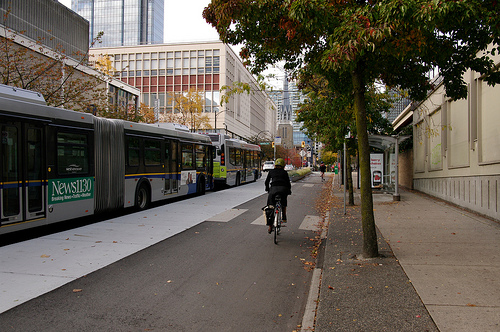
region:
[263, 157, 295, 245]
person riding a bicycle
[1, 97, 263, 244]
Buses parked on side of street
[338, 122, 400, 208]
bus stop protected from weather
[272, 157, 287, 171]
hat on persons head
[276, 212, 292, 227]
persons foot on bicycle peddle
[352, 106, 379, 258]
trunk of tree on side of road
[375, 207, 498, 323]
white concrete sidewalk sections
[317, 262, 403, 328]
asphalt between sidewalk and curb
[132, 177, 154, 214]
large rear tire on bus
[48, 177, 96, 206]
billboard on side of bus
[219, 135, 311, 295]
person riding bike down the street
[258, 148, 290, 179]
person is wearing a helmet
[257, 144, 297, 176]
the helmet is grey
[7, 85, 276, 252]
city buses on the street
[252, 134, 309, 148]
the light is green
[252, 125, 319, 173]
traffic lights in the distance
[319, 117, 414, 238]
the bus stop up ahead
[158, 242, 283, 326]
the street is black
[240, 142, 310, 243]
the person is wearing black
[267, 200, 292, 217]
the brake light is red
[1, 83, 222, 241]
very long gray bus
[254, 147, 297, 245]
back view of person on bicycle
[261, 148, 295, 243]
person wearing light colored helmet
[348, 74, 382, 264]
one brown tree trunk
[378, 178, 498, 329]
broad white sidewalk next to building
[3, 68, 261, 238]
two buses parked at curb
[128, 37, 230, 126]
several square building windows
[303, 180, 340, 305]
dead brown leaves at curb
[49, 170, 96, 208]
green and white News 1130 sign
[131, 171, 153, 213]
large black bus wheel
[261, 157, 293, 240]
a man on bicycle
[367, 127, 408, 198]
an outdoor bus shelter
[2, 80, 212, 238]
a double public service bus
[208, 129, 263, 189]
a white public service bus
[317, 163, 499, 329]
a paved city sidewalk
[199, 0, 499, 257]
a small green tree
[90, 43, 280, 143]
a large tan building in distance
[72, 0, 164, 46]
a tall building in distance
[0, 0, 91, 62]
a grey building in distance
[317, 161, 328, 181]
a pedestrian in street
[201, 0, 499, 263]
a tree surrounded by sidewalk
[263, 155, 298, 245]
a person on a bike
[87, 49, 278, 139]
a building covered in windows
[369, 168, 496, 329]
a section of sidewalk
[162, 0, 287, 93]
a section of sky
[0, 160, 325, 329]
a long section of street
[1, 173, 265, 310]
some white colored sidewalk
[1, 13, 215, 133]
the tops of trees in the background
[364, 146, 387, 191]
a large white sign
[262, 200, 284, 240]
a bicycle being ridden